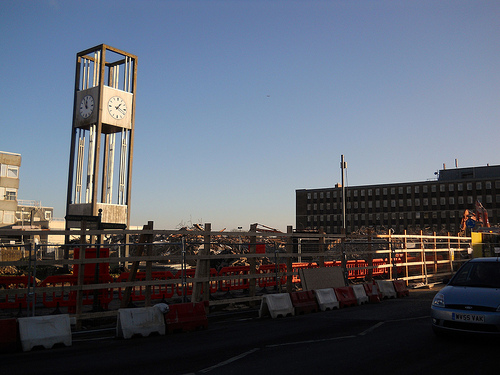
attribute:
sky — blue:
[209, 22, 460, 133]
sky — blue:
[162, 38, 270, 160]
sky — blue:
[160, 17, 388, 138]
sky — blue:
[283, 50, 387, 102]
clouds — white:
[190, 82, 220, 113]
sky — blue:
[216, 40, 375, 136]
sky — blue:
[0, 0, 496, 244]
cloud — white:
[260, 88, 277, 104]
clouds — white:
[237, 101, 265, 121]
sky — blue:
[10, 0, 496, 159]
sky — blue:
[199, 26, 369, 126]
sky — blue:
[223, 40, 314, 116]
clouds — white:
[282, 13, 439, 108]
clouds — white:
[201, 107, 352, 182]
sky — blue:
[276, 45, 492, 129]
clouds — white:
[208, 70, 432, 162]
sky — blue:
[29, 10, 453, 185]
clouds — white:
[258, 128, 344, 185]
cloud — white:
[41, 192, 296, 232]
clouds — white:
[433, 87, 498, 141]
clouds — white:
[132, 200, 290, 224]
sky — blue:
[2, 1, 479, 265]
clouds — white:
[140, 191, 291, 237]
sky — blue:
[0, 3, 476, 221]